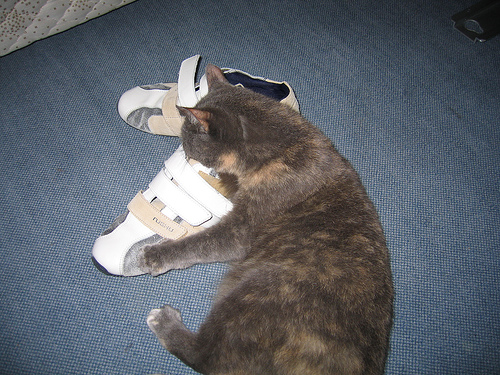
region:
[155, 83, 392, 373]
cat laying on ground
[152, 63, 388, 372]
cat looking at shoe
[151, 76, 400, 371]
cat distracted by shoe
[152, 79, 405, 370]
cat laying on its side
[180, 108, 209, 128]
ear of cat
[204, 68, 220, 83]
ear of cat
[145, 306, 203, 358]
paw of cat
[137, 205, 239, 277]
grey leg of cat by shoe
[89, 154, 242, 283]
white shoe under cat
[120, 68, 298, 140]
white shoe by cat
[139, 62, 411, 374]
Dark colored cat sitting on the sofa.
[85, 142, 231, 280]
Shoe with three straps across the top.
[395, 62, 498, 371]
Blue sofa cushion.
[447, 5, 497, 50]
Metal piece of hardware on the cushion.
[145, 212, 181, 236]
Name brand of the shoe written on the strap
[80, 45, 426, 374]
Cat putting it's face into a shoe.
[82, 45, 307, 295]
A pair of shoes sitting on the sofa.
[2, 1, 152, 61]
White fabric with spots on it.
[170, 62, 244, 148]
Pink ears of the cat.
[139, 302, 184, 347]
Cat's paw with white fur.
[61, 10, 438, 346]
Cat playing with a shoe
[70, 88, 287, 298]
Cat with its head inside of a shoe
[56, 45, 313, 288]
White and grey shoes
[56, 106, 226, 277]
Shoe has velcro straps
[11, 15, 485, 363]
Blue carpet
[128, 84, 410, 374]
Brown cat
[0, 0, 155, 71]
Part of a mattress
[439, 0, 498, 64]
Metal piece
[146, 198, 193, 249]
Brand name of shoe on front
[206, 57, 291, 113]
Inside shoe is dark blue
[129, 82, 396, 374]
a cat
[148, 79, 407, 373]
a cat on a blue surface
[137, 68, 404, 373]
the cat is sniffing a shoe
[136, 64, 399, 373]
the cat's face is buried in the shoe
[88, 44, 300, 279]
the sneakers have Velcro laces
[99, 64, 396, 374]
the cat is on the sneaker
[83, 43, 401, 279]
a pair of sneakers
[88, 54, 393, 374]
a pair of sneakers are under the cat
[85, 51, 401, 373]
the cat is playing with the sneaker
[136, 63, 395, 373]
the cat is brown and grey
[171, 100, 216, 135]
the ear of a cat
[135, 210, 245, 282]
the leg of a cat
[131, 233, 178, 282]
the paw of a cat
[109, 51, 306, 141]
a white shoe on the ground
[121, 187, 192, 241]
a brown strap on the shoe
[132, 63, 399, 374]
a gray and brown cat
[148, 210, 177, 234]
writing on the strap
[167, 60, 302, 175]
the head of a cat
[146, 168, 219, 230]
a white strap on the shoe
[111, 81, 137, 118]
the toe of a shoe